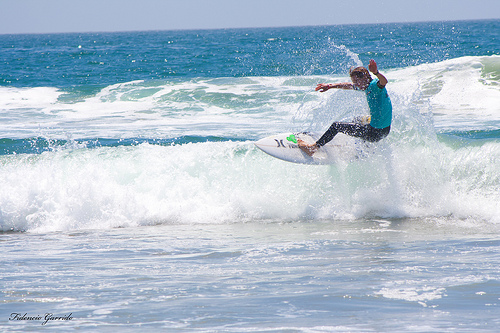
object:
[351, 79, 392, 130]
rashguard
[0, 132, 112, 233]
waves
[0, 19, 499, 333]
ocean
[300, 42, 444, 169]
spray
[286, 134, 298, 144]
sticker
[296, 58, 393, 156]
boarder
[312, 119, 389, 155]
pants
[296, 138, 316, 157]
foot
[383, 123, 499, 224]
waves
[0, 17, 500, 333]
water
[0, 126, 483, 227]
wave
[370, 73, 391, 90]
arms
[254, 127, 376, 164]
board